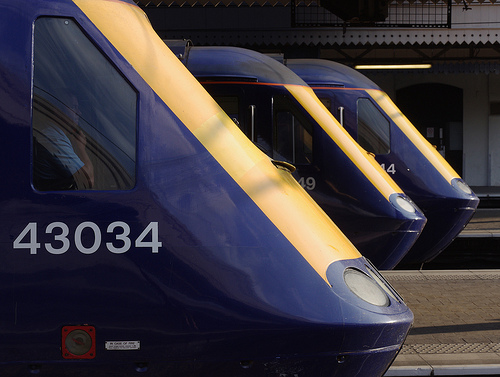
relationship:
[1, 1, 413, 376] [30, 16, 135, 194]
train has window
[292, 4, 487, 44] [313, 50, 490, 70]
grate above awning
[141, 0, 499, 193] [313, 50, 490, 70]
building has awning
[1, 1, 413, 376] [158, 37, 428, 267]
train next to train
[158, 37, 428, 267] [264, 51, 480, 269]
train next to train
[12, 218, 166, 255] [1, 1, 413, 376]
numbers on train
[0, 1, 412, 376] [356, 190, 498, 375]
train parked on tracks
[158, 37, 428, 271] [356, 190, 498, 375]
train parked on tracks